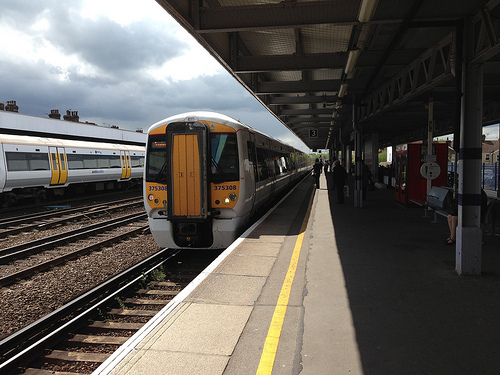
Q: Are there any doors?
A: Yes, there are doors.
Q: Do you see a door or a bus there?
A: Yes, there are doors.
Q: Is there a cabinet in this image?
A: No, there are no cabinets.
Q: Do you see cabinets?
A: No, there are no cabinets.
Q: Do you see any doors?
A: Yes, there are doors.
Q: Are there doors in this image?
A: Yes, there are doors.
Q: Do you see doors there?
A: Yes, there are doors.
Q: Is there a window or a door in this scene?
A: Yes, there are doors.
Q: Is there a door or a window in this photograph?
A: Yes, there are doors.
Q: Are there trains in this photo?
A: Yes, there is a train.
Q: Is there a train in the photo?
A: Yes, there is a train.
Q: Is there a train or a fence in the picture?
A: Yes, there is a train.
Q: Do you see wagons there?
A: No, there are no wagons.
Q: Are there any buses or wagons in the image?
A: No, there are no wagons or buses.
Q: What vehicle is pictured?
A: The vehicle is a train.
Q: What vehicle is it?
A: The vehicle is a train.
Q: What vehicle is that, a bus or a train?
A: This is a train.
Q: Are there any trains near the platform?
A: Yes, there is a train near the platform.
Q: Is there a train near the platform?
A: Yes, there is a train near the platform.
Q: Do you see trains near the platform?
A: Yes, there is a train near the platform.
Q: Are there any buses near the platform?
A: No, there is a train near the platform.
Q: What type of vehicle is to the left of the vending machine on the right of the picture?
A: The vehicle is a train.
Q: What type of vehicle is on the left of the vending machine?
A: The vehicle is a train.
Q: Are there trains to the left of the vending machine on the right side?
A: Yes, there is a train to the left of the vending machine.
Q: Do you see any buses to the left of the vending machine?
A: No, there is a train to the left of the vending machine.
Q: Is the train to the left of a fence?
A: No, the train is to the left of the vending machine.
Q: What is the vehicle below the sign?
A: The vehicle is a train.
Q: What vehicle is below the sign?
A: The vehicle is a train.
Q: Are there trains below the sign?
A: Yes, there is a train below the sign.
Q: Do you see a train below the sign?
A: Yes, there is a train below the sign.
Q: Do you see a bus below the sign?
A: No, there is a train below the sign.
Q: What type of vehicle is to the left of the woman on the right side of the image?
A: The vehicle is a train.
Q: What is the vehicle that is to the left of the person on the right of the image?
A: The vehicle is a train.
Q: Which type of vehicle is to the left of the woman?
A: The vehicle is a train.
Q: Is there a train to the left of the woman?
A: Yes, there is a train to the left of the woman.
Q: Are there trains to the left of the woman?
A: Yes, there is a train to the left of the woman.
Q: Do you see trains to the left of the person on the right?
A: Yes, there is a train to the left of the woman.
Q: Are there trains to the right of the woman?
A: No, the train is to the left of the woman.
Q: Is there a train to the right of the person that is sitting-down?
A: No, the train is to the left of the woman.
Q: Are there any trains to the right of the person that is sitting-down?
A: No, the train is to the left of the woman.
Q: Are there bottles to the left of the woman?
A: No, there is a train to the left of the woman.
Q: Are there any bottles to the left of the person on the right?
A: No, there is a train to the left of the woman.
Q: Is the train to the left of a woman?
A: Yes, the train is to the left of a woman.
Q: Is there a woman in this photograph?
A: Yes, there is a woman.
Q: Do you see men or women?
A: Yes, there is a woman.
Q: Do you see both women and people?
A: Yes, there are both a woman and a person.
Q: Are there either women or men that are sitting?
A: Yes, the woman is sitting.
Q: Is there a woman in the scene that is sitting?
A: Yes, there is a woman that is sitting.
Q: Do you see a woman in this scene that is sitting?
A: Yes, there is a woman that is sitting.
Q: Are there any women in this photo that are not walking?
A: Yes, there is a woman that is sitting.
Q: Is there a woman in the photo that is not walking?
A: Yes, there is a woman that is sitting.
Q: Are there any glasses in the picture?
A: No, there are no glasses.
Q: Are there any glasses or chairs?
A: No, there are no glasses or chairs.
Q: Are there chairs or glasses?
A: No, there are no glasses or chairs.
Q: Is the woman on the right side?
A: Yes, the woman is on the right of the image.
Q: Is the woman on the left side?
A: No, the woman is on the right of the image.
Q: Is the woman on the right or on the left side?
A: The woman is on the right of the image.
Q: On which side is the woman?
A: The woman is on the right of the image.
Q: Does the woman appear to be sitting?
A: Yes, the woman is sitting.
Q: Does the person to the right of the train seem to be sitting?
A: Yes, the woman is sitting.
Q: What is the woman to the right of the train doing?
A: The woman is sitting.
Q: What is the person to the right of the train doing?
A: The woman is sitting.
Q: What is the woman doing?
A: The woman is sitting.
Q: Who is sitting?
A: The woman is sitting.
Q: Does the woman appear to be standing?
A: No, the woman is sitting.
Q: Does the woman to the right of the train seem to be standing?
A: No, the woman is sitting.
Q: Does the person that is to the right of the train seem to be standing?
A: No, the woman is sitting.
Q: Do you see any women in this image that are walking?
A: No, there is a woman but she is sitting.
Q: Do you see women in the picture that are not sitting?
A: No, there is a woman but she is sitting.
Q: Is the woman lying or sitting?
A: The woman is sitting.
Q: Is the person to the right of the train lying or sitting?
A: The woman is sitting.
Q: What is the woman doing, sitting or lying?
A: The woman is sitting.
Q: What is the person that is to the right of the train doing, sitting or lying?
A: The woman is sitting.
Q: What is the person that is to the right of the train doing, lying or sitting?
A: The woman is sitting.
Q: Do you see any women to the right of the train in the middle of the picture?
A: Yes, there is a woman to the right of the train.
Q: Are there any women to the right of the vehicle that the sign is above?
A: Yes, there is a woman to the right of the train.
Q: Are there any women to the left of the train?
A: No, the woman is to the right of the train.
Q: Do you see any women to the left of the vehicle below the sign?
A: No, the woman is to the right of the train.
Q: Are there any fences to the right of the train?
A: No, there is a woman to the right of the train.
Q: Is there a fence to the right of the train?
A: No, there is a woman to the right of the train.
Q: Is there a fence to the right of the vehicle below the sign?
A: No, there is a woman to the right of the train.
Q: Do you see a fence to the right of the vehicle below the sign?
A: No, there is a woman to the right of the train.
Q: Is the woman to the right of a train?
A: Yes, the woman is to the right of a train.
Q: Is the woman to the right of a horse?
A: No, the woman is to the right of a train.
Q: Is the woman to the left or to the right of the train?
A: The woman is to the right of the train.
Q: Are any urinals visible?
A: No, there are no urinals.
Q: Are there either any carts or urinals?
A: No, there are no urinals or carts.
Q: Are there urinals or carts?
A: No, there are no urinals or carts.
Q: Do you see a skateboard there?
A: No, there are no skateboards.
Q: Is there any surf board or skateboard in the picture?
A: No, there are no skateboards or surfboards.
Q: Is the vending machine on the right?
A: Yes, the vending machine is on the right of the image.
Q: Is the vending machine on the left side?
A: No, the vending machine is on the right of the image.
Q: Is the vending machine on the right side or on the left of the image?
A: The vending machine is on the right of the image.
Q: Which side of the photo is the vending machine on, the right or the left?
A: The vending machine is on the right of the image.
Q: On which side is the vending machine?
A: The vending machine is on the right of the image.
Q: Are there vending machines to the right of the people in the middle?
A: Yes, there is a vending machine to the right of the people.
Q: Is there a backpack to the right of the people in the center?
A: No, there is a vending machine to the right of the people.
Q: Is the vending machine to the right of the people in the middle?
A: Yes, the vending machine is to the right of the people.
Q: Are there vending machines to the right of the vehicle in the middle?
A: Yes, there is a vending machine to the right of the train.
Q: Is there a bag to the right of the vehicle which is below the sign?
A: No, there is a vending machine to the right of the train.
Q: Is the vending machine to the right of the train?
A: Yes, the vending machine is to the right of the train.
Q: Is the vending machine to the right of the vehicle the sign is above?
A: Yes, the vending machine is to the right of the train.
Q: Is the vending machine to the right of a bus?
A: No, the vending machine is to the right of the train.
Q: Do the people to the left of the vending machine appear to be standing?
A: Yes, the people are standing.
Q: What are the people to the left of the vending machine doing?
A: The people are standing.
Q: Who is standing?
A: The people are standing.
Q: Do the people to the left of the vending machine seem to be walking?
A: No, the people are standing.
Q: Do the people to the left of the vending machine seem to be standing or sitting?
A: The people are standing.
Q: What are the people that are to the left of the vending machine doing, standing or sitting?
A: The people are standing.